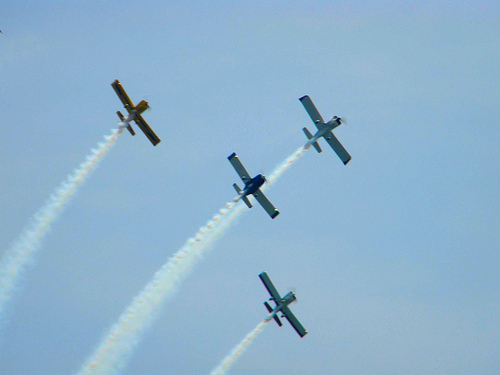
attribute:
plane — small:
[248, 270, 310, 339]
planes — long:
[214, 94, 358, 347]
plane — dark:
[107, 75, 159, 146]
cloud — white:
[0, 97, 313, 372]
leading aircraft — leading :
[297, 95, 353, 167]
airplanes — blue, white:
[222, 149, 287, 216]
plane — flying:
[259, 272, 306, 338]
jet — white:
[297, 93, 350, 165]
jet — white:
[228, 149, 279, 223]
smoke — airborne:
[15, 123, 193, 353]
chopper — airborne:
[295, 95, 354, 165]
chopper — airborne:
[105, 74, 162, 146]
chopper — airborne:
[227, 149, 280, 219]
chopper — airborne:
[255, 267, 307, 338]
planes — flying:
[298, 94, 356, 164]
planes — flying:
[226, 151, 279, 221]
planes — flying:
[110, 79, 161, 146]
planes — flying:
[258, 272, 310, 337]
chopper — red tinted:
[241, 64, 392, 211]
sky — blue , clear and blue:
[3, 0, 499, 371]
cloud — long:
[65, 169, 270, 371]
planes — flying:
[288, 101, 360, 168]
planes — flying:
[105, 80, 155, 132]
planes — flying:
[222, 149, 286, 209]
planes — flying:
[251, 268, 303, 338]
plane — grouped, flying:
[88, 56, 413, 361]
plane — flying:
[226, 151, 279, 219]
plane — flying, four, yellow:
[110, 74, 160, 149]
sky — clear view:
[419, 30, 480, 159]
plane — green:
[289, 82, 376, 186]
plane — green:
[209, 140, 301, 229]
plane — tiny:
[100, 74, 163, 148]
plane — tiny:
[215, 147, 277, 222]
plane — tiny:
[287, 87, 359, 171]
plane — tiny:
[252, 267, 312, 344]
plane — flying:
[298, 92, 350, 164]